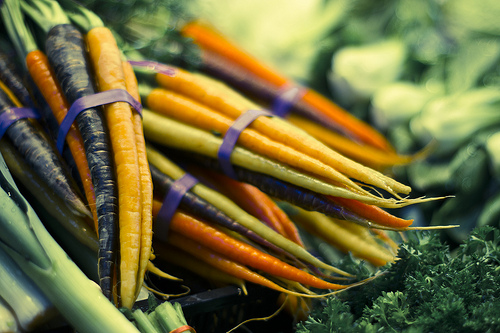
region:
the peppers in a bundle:
[141, 46, 394, 241]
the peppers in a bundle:
[151, 175, 346, 306]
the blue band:
[52, 71, 142, 146]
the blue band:
[195, 90, 275, 178]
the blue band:
[1, 102, 37, 130]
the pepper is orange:
[165, 60, 345, 186]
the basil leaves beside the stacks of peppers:
[277, 241, 498, 331]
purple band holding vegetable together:
[197, 97, 274, 172]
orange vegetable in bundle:
[25, 53, 109, 205]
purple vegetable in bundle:
[51, 28, 120, 263]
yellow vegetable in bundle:
[142, 108, 319, 175]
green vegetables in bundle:
[137, 298, 198, 328]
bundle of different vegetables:
[27, 18, 162, 265]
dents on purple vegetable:
[77, 131, 117, 178]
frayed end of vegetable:
[356, 170, 446, 232]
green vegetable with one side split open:
[6, 196, 62, 283]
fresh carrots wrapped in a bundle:
[24, 13, 428, 298]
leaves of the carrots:
[295, 220, 498, 327]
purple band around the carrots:
[50, 85, 149, 144]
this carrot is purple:
[42, 19, 124, 299]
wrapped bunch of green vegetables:
[142, 303, 187, 331]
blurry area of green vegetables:
[329, 20, 498, 180]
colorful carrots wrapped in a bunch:
[3, 1, 424, 313]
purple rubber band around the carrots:
[213, 107, 272, 180]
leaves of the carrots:
[0, 1, 101, 66]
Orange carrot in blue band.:
[134, 168, 166, 239]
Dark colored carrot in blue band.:
[71, 86, 108, 161]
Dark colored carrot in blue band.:
[21, 144, 51, 169]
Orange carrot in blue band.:
[166, 100, 215, 119]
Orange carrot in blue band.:
[198, 82, 226, 101]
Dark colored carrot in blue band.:
[225, 68, 257, 79]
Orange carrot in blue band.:
[217, 37, 248, 64]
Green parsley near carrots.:
[391, 255, 441, 310]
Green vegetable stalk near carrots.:
[25, 225, 75, 293]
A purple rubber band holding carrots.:
[214, 105, 280, 177]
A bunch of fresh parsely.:
[420, 255, 485, 315]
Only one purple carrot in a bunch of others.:
[53, 14, 115, 310]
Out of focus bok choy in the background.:
[332, 2, 499, 85]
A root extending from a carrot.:
[228, 294, 293, 331]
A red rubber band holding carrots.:
[164, 325, 199, 331]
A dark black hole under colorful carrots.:
[202, 296, 287, 330]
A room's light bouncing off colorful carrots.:
[32, 51, 84, 93]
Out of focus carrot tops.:
[130, 7, 185, 62]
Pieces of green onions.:
[7, 214, 43, 331]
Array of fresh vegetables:
[1, 0, 496, 331]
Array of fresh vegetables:
[31, 96, 342, 293]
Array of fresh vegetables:
[4, 3, 209, 332]